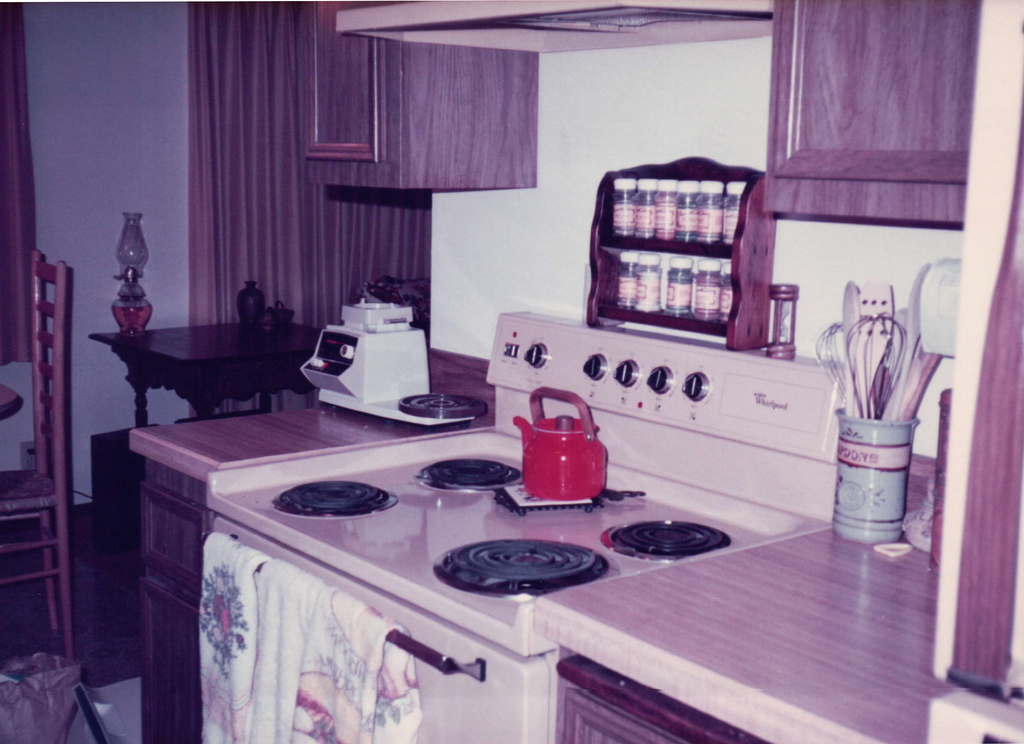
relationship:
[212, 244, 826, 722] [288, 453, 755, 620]
oven with burners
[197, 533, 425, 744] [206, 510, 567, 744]
cloths hanging on oven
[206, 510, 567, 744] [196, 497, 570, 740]
oven of oven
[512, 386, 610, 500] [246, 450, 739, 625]
kettle over stove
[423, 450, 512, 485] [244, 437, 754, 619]
burner on stove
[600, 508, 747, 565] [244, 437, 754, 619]
burner on stove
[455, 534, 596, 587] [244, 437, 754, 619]
burner on stove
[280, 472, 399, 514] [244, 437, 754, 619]
burner on stove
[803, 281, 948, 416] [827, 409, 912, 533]
utensils in can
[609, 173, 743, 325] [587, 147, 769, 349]
spices on rack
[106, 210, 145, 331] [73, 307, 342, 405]
lamp over table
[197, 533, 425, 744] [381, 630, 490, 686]
cloths on handle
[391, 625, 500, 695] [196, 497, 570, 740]
handle of oven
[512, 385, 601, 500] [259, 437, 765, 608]
kettle on stove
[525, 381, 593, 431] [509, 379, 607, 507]
handle of kettle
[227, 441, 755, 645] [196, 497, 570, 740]
stove above oven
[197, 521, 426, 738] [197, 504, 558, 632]
cloths on oven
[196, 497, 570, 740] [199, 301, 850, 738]
oven under stove